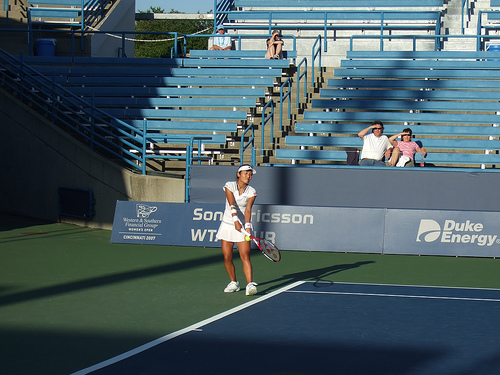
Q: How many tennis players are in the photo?
A: One.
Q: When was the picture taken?
A: Daytime.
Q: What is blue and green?
A: Tennis court.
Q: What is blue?
A: Bleachers.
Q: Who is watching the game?
A: Spectators.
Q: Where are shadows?
A: On the court.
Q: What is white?
A: Tennis player's outfit.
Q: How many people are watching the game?
A: Four.